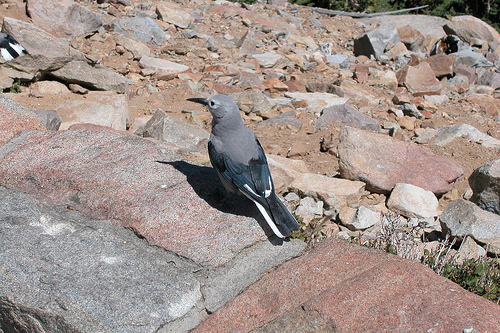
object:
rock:
[287, 171, 364, 201]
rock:
[397, 61, 443, 96]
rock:
[437, 195, 498, 255]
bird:
[185, 94, 301, 239]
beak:
[185, 97, 206, 106]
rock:
[140, 107, 212, 151]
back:
[218, 128, 258, 173]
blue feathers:
[208, 142, 276, 239]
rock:
[353, 29, 388, 57]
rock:
[251, 50, 283, 66]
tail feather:
[258, 200, 288, 239]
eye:
[211, 101, 215, 106]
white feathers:
[247, 187, 287, 244]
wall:
[1, 95, 498, 330]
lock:
[339, 125, 462, 193]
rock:
[113, 11, 172, 47]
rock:
[137, 54, 192, 79]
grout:
[158, 237, 303, 330]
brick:
[192, 240, 497, 332]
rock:
[2, 120, 289, 332]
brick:
[386, 182, 442, 219]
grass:
[417, 233, 466, 277]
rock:
[360, 12, 401, 59]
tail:
[257, 191, 300, 239]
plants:
[412, 247, 497, 307]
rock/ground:
[395, 60, 442, 99]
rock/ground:
[335, 120, 462, 195]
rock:
[0, 12, 99, 72]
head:
[206, 92, 238, 123]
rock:
[391, 180, 443, 220]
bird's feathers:
[252, 191, 301, 239]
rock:
[335, 123, 472, 193]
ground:
[244, 15, 476, 316]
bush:
[421, 237, 499, 301]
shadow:
[152, 158, 291, 244]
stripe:
[242, 182, 264, 199]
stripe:
[262, 173, 272, 196]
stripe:
[237, 188, 287, 240]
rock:
[384, 181, 442, 220]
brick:
[2, 191, 196, 333]